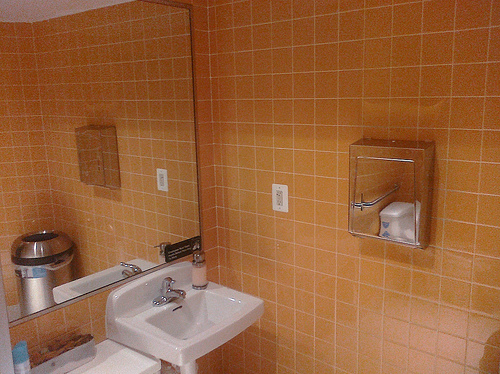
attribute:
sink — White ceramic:
[97, 243, 267, 360]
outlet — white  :
[266, 173, 303, 226]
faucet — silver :
[152, 274, 185, 306]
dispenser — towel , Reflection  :
[324, 135, 461, 268]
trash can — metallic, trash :
[3, 222, 91, 314]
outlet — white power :
[153, 167, 170, 194]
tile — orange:
[267, 250, 456, 362]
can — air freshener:
[8, 338, 38, 370]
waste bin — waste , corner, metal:
[8, 227, 77, 316]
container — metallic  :
[334, 127, 438, 259]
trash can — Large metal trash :
[17, 228, 74, 308]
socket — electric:
[155, 165, 168, 192]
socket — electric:
[269, 180, 288, 215]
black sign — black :
[163, 234, 200, 262]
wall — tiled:
[222, 10, 489, 140]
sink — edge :
[87, 246, 273, 367]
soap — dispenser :
[187, 245, 212, 292]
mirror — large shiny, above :
[3, 2, 205, 326]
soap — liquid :
[187, 249, 209, 298]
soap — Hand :
[191, 239, 212, 290]